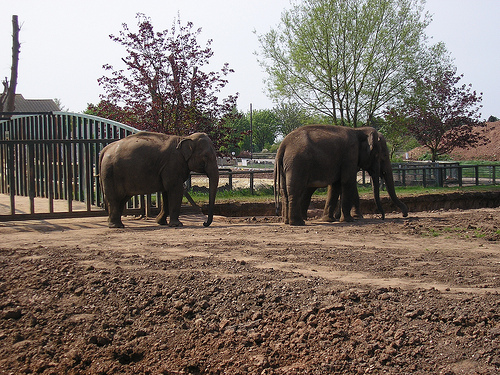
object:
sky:
[4, 12, 500, 118]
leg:
[338, 180, 358, 222]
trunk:
[202, 165, 222, 227]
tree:
[254, 2, 456, 168]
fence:
[0, 110, 169, 219]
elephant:
[97, 131, 220, 228]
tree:
[86, 6, 242, 154]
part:
[325, 32, 373, 71]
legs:
[166, 187, 184, 228]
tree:
[247, 108, 279, 154]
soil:
[0, 199, 500, 374]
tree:
[383, 65, 495, 167]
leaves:
[380, 64, 496, 160]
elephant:
[272, 126, 385, 225]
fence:
[392, 160, 500, 187]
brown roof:
[3, 98, 61, 115]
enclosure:
[3, 113, 496, 370]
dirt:
[1, 204, 498, 372]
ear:
[174, 138, 195, 160]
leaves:
[251, 1, 458, 151]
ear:
[364, 130, 378, 154]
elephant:
[270, 121, 409, 227]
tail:
[271, 155, 280, 209]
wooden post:
[193, 164, 500, 194]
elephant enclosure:
[0, 110, 497, 222]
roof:
[0, 91, 63, 114]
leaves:
[162, 7, 219, 82]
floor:
[117, 258, 374, 336]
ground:
[0, 248, 500, 375]